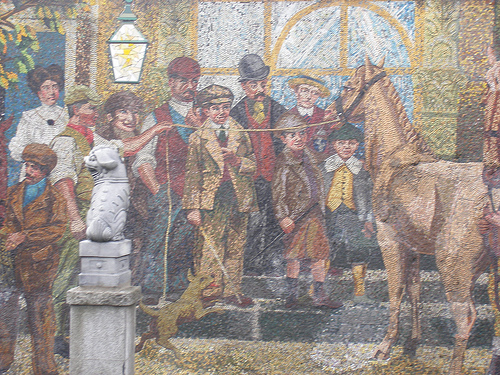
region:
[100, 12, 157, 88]
a lantern above a man.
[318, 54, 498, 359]
a brown horse.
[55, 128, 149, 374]
a tall white statue.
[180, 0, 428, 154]
a large window.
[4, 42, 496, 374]
a crowd of people meeting.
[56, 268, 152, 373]
a support for a sculpture.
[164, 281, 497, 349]
a black line on the ground.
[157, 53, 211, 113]
a man in a red hat.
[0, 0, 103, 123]
a tree with lots of leaves.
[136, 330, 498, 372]
a brown section of ground.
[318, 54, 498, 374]
brown horse wearing bridle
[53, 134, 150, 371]
carved stone statue atop pedestal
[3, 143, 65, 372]
man wearing brown with a blue scarf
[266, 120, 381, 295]
young boys admiring a horse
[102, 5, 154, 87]
glass and metal street lamp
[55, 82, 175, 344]
jockey holding horses reins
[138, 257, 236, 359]
small brown dog barking at horse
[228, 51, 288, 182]
mustachioed man in bowler hat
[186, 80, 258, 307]
boy wearing brown suit and black tie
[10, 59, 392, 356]
group of people admiring a horse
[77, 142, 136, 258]
gray stone dog statue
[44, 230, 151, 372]
gray stone statue pedestal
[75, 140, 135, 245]
stone dog looking left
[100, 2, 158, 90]
streetlight hanging on wall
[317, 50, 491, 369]
brown horse looking left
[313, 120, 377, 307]
boy in yellow vest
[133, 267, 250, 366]
jumping brown dog on street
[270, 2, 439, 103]
arched window in background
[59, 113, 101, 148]
red scarf on man's neck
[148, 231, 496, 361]
stone steps in front of building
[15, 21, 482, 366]
This is a painting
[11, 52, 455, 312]
This is not America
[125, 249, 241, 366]
Dog by the steps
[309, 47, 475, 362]
A brown horse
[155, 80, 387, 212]
Horse is on a leash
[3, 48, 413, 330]
People are looking at horse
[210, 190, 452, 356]
The steps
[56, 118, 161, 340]
A statue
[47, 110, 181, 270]
This is a dog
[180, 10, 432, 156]
Painting on a building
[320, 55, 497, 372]
a brown horse near a painting.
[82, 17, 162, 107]
a lantern above a crowd.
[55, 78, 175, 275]
a person in a room.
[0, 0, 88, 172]
leaves on a green tree.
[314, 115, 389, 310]
a man standing near a horse.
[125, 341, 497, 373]
the ground under a crowd.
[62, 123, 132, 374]
a white statue near a crowd.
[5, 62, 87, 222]
a woman wearing white.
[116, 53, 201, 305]
a man in a vest.